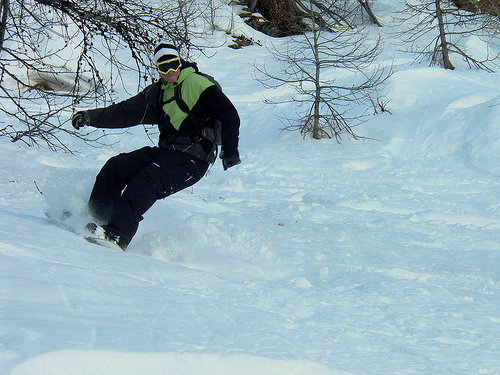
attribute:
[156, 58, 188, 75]
goggles — black, yellow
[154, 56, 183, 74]
snow glasses — yellow, black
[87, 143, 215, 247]
snow pants — black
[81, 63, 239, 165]
coat — black, green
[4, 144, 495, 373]
snow — white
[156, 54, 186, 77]
googles — black, yellow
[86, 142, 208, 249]
pants — black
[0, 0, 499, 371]
snow — white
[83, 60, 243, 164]
jacket — green and black, black and green, green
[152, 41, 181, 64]
hat — black and white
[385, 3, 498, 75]
tree — leafless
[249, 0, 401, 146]
tree — leafless